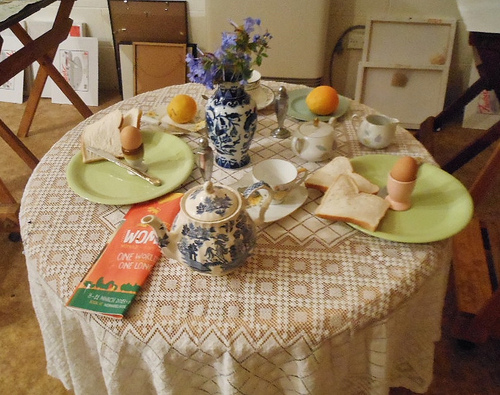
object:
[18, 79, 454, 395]
table cloth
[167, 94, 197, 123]
orange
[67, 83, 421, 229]
food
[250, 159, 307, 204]
cup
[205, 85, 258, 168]
shakers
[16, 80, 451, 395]
table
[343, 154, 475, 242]
green plate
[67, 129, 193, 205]
green plate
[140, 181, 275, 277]
tea kettle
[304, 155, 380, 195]
bread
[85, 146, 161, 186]
knife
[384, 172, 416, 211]
cup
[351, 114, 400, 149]
creamer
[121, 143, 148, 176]
egg holders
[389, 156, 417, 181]
eggs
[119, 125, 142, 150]
eggs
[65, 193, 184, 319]
paper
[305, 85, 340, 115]
grapefruit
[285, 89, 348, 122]
plate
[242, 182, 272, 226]
handle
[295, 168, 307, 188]
handle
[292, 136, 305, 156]
handle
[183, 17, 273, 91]
flowers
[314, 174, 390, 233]
bread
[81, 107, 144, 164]
bread